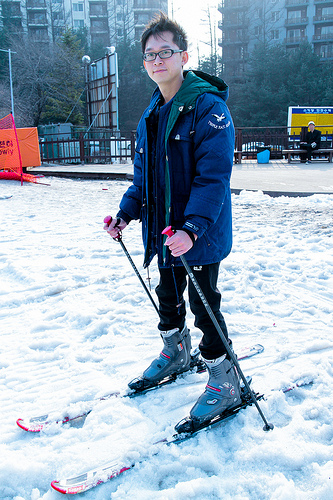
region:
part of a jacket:
[187, 179, 212, 207]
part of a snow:
[204, 464, 240, 491]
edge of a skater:
[56, 485, 85, 498]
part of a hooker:
[239, 394, 270, 432]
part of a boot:
[190, 396, 220, 410]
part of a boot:
[198, 359, 229, 398]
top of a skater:
[86, 468, 111, 485]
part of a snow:
[201, 429, 246, 463]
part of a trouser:
[208, 332, 218, 358]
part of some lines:
[55, 376, 103, 410]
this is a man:
[94, 29, 259, 401]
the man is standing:
[90, 22, 252, 407]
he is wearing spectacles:
[135, 44, 180, 63]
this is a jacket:
[132, 87, 220, 209]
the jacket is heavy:
[138, 92, 224, 209]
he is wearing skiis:
[23, 387, 136, 495]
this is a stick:
[184, 299, 230, 330]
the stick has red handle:
[159, 223, 177, 239]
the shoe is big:
[200, 365, 232, 416]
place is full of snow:
[6, 288, 104, 385]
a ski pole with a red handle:
[102, 213, 161, 323]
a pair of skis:
[15, 342, 314, 495]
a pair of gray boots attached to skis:
[125, 326, 247, 433]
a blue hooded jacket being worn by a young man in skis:
[116, 68, 234, 263]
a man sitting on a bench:
[298, 119, 323, 164]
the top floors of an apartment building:
[218, 1, 331, 61]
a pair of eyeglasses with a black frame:
[141, 48, 183, 60]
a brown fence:
[38, 131, 135, 163]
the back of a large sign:
[83, 47, 119, 132]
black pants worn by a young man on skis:
[155, 260, 231, 362]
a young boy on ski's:
[24, 12, 303, 496]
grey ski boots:
[140, 321, 251, 431]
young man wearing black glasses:
[131, 15, 193, 80]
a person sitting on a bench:
[285, 119, 330, 160]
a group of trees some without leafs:
[6, 25, 104, 137]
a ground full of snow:
[5, 175, 329, 372]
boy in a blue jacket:
[91, 12, 256, 273]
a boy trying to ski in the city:
[9, 4, 331, 484]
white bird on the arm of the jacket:
[205, 109, 233, 131]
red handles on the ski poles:
[96, 202, 198, 262]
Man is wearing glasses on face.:
[135, 50, 211, 69]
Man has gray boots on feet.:
[151, 355, 256, 442]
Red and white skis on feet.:
[51, 406, 143, 496]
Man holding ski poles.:
[95, 216, 241, 282]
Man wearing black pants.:
[144, 270, 245, 334]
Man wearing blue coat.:
[122, 107, 267, 216]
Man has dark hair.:
[145, 21, 217, 45]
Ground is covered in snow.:
[30, 261, 105, 354]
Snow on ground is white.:
[171, 448, 290, 485]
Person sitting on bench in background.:
[297, 118, 330, 175]